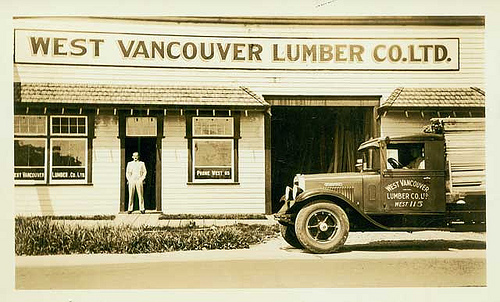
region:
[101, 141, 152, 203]
man is in doorway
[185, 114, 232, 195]
dark frame around windows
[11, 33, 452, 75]
black frame around sign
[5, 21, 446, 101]
dark letters on sign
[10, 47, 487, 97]
light siding on building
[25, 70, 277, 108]
small awning over man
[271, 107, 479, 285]
truck next to man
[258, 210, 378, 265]
truck has dark wheels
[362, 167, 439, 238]
company name on driver's door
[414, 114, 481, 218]
load carried in truck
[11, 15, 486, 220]
white and black building behind truck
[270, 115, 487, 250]
dark colored truck in front of building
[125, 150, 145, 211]
man standing in doorway of building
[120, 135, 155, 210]
open doorway of building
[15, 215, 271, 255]
large patch of plants in front of man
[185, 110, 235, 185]
glass window on building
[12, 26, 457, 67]
long sign on building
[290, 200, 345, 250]
black tire on truck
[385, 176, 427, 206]
words on door of truck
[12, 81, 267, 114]
shingled awning on building above man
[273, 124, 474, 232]
this is a lorry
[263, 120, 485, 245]
the lorry is parked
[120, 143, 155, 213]
this is a man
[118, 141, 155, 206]
the man is standing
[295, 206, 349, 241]
this is the wheel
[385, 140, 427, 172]
the window is open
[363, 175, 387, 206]
the lorry is old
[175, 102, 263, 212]
this is a cafe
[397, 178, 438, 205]
the lorry is black in color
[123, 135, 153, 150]
the door is open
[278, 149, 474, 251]
vehicle parked in front of the house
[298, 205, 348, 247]
Tyre of the vehicle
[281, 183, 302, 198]
Head lights of the vehicle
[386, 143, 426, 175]
Driver holding the steering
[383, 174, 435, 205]
Driver side door of the vehicle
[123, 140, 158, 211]
A person standing in the entrance of the house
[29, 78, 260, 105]
Roof of the house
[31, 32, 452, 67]
Company name board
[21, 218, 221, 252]
Small plants near the house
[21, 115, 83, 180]
Windows of the house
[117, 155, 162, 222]
a man standing in doorway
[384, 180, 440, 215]
white lettering on a truck door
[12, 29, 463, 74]
a store name on large sign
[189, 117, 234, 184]
a glass paned window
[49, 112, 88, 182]
a glass paned window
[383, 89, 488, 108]
tiles on the roof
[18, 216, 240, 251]
a strip of tall grass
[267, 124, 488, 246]
an old fashioned truck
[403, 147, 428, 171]
a person driving a truck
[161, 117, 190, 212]
clap boards on the wall